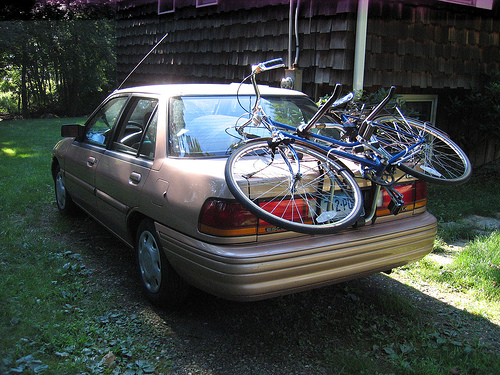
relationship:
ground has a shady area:
[2, 114, 500, 372] [4, 117, 496, 370]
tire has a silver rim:
[132, 221, 192, 316] [137, 229, 162, 295]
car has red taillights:
[53, 81, 439, 303] [196, 179, 435, 241]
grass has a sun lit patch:
[2, 120, 500, 372] [380, 193, 500, 327]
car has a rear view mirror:
[53, 81, 439, 303] [148, 100, 161, 107]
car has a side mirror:
[53, 81, 439, 303] [61, 125, 83, 139]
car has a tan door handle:
[53, 81, 439, 303] [87, 156, 98, 164]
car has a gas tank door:
[53, 81, 439, 303] [153, 178, 172, 206]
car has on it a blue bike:
[53, 81, 439, 303] [225, 56, 474, 233]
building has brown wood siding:
[116, 2, 496, 200] [328, 33, 355, 50]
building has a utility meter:
[116, 2, 496, 200] [280, 68, 302, 96]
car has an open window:
[53, 81, 439, 303] [115, 94, 158, 155]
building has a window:
[116, 2, 496, 200] [157, 3, 177, 15]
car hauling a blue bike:
[53, 81, 439, 303] [225, 56, 474, 233]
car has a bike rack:
[53, 81, 439, 303] [292, 83, 403, 229]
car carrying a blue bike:
[53, 81, 439, 303] [225, 56, 474, 233]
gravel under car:
[74, 207, 447, 350] [53, 81, 439, 303]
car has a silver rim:
[53, 81, 439, 303] [137, 229, 162, 295]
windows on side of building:
[157, 2, 219, 16] [116, 2, 496, 200]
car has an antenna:
[53, 81, 439, 303] [82, 31, 168, 109]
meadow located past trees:
[0, 66, 60, 113] [2, 5, 120, 123]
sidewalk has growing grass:
[425, 210, 497, 265] [2, 120, 500, 372]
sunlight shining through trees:
[2, 66, 64, 121] [2, 5, 120, 123]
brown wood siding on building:
[328, 33, 355, 50] [116, 2, 496, 200]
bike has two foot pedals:
[225, 56, 474, 233] [357, 122, 405, 217]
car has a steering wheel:
[53, 81, 439, 303] [118, 119, 146, 148]